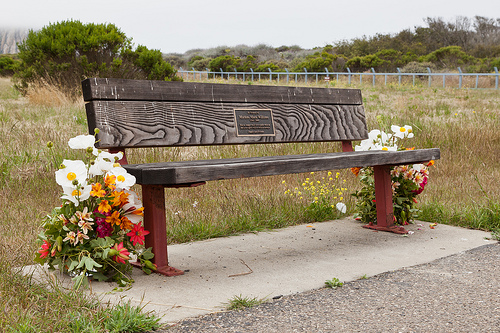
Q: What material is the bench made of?
A: Wood.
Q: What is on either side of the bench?
A: Flowers.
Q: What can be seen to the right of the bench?
A: A fence.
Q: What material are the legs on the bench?
A: Metal.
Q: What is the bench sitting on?
A: Concrete.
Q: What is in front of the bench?
A: Walkway.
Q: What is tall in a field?
A: Grass.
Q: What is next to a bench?
A: Two bouquet of flowers.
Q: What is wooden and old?
A: The seat.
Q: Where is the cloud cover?
A: Sky.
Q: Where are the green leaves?
A: Bush.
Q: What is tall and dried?
A: Grass surface.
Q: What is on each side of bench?
A: Flowers.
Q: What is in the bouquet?
A: Colorful flowers.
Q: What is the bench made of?
A: Weathered wood.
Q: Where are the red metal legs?
A: Bench.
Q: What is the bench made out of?
A: Wood.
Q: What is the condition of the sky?
A: Overcast.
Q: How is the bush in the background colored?
A: Green.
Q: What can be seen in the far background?
A: Treeline.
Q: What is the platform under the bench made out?
A: Cement.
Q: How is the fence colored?
A: Gray.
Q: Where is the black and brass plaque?
A: Back of bench.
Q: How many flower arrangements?
A: Two.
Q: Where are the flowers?
A: Beside the bench.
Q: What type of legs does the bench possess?
A: Metal.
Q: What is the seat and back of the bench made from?
A: Wood.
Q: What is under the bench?
A: Concrete.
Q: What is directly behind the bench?
A: Field.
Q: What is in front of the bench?
A: Gravel.